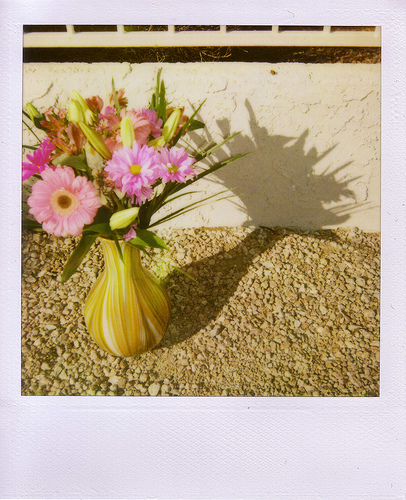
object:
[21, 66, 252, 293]
boquet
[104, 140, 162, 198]
flower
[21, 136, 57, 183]
flower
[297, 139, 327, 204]
ground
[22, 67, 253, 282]
flowers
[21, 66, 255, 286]
flower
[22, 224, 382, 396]
gravel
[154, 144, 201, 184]
flower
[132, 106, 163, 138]
flower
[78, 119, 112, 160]
bud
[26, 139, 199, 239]
flowers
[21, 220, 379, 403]
ground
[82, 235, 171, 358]
patches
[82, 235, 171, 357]
base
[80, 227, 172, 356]
vase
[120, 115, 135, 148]
bud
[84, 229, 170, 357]
pot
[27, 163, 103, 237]
flower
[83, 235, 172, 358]
yellow vase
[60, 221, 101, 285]
leaf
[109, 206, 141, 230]
bud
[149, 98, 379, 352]
shadow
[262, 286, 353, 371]
gravel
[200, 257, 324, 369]
gravel